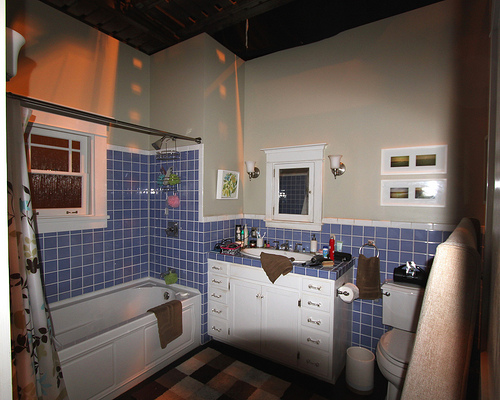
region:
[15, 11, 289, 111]
A slatted ceiling letting orange light into the bathroom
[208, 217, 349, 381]
A sink and countertop with many beauty products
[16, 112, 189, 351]
A bathtub and shower with a window inside it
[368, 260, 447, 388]
A clean white toilet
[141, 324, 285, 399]
A large patchwork bath mat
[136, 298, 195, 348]
A towel draped over the bathtub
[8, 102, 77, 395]
A shower curtain drawn to the left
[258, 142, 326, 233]
A white-framed mirror and medicine cabinet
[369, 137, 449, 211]
A set of photos on display above the toilet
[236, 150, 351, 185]
Small vanity lights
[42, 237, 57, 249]
a tile on a wall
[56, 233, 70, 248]
a tile on a wall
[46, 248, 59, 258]
a tile on a wall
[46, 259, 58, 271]
a tile on a wall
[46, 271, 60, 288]
a tile on a wall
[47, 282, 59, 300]
a tile on a wall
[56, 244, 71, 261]
a tile on a wall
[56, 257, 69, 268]
a tile on a wall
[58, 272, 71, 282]
a tile on a wall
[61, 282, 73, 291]
a tile on a wall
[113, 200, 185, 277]
Blue tiles on the bathroom wall.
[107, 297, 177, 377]
Tub is white in color.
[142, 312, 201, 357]
Brown bath mat draped over edge of tub.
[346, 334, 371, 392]
White oval shaped garbage can.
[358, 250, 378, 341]
Brown hand towel on holder.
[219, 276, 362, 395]
White vanity cabinet in bathroom.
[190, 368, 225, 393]
Multi colored bath mat in front of vanity.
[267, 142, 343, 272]
Mirror is framed in white.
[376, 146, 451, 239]
Two frames above the toilet.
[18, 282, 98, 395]
Shower curtain has a floral design.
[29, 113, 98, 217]
A bathroom window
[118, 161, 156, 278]
Blue bathroom tiles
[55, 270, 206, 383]
A white bathtub with a brown towel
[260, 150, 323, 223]
A white bathroom mirror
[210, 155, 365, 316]
A painting hanging in a bathroom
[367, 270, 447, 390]
A white toilet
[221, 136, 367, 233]
Two bathroom lights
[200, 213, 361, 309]
A bathroom sink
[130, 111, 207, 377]
A shower with blue tiles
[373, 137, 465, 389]
Two paintings hanging above a toilet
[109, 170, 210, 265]
Blue tile on a wall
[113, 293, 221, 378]
Towel on a bathtub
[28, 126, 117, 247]
Window in a bathroom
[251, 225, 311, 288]
Towel on a sink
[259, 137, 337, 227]
Mirror on a wall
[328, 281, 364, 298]
Toilet paper by a toilet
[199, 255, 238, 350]
Drawers by a sink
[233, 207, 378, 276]
Bottles on a counter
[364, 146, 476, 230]
Pictures on a wall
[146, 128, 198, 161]
Shower head in a shower